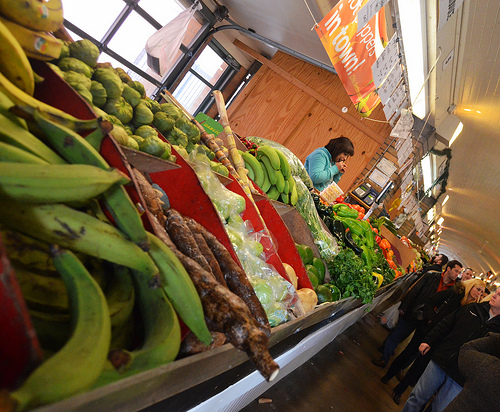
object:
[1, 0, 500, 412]
farmers market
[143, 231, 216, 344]
banana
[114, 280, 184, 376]
banana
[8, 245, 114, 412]
banana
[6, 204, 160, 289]
banana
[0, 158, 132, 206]
banana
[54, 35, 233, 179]
fruit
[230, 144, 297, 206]
fruit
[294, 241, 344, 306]
fruit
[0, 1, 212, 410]
fruit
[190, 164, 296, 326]
fruit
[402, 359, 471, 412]
jeans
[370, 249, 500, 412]
group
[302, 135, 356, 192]
woman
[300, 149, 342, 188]
top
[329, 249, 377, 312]
vegetables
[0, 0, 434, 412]
food